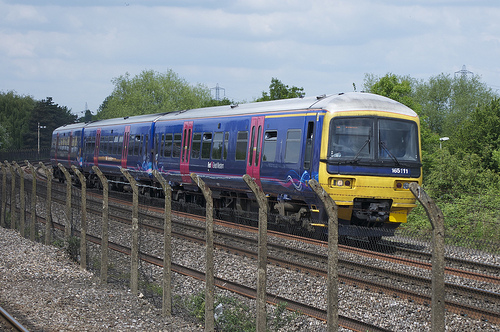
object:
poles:
[408, 181, 446, 331]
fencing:
[450, 245, 499, 332]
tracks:
[111, 205, 238, 251]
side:
[99, 200, 199, 246]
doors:
[247, 118, 260, 176]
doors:
[179, 125, 192, 185]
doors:
[121, 125, 129, 164]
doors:
[91, 131, 101, 162]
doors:
[67, 131, 74, 166]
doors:
[54, 136, 59, 163]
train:
[52, 124, 413, 239]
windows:
[250, 122, 262, 165]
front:
[318, 102, 423, 237]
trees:
[417, 97, 498, 219]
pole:
[37, 123, 41, 158]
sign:
[38, 120, 48, 130]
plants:
[217, 297, 254, 332]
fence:
[2, 174, 497, 331]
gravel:
[0, 247, 110, 331]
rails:
[1, 307, 24, 330]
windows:
[332, 120, 418, 165]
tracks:
[412, 261, 465, 274]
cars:
[51, 92, 420, 243]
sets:
[396, 289, 498, 324]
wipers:
[355, 138, 399, 159]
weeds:
[172, 289, 203, 326]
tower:
[452, 64, 473, 83]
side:
[49, 112, 321, 221]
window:
[59, 130, 301, 158]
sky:
[2, 9, 489, 69]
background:
[0, 0, 50, 155]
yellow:
[319, 111, 423, 225]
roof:
[48, 92, 418, 133]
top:
[212, 82, 224, 87]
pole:
[215, 83, 221, 102]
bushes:
[423, 139, 499, 223]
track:
[218, 241, 277, 259]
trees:
[4, 95, 36, 168]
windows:
[194, 135, 227, 163]